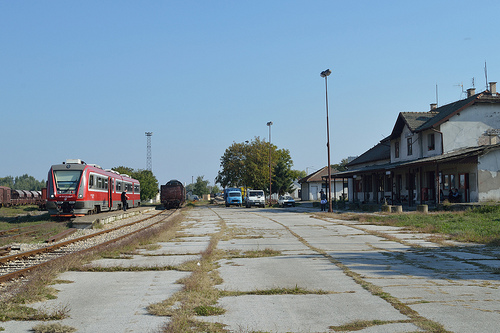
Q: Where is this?
A: This is at the road.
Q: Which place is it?
A: It is a road.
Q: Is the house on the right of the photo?
A: Yes, the house is on the right of the image.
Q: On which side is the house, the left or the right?
A: The house is on the right of the image.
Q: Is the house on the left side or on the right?
A: The house is on the right of the image.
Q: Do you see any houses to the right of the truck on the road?
A: Yes, there is a house to the right of the truck.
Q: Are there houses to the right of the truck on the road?
A: Yes, there is a house to the right of the truck.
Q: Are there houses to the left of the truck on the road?
A: No, the house is to the right of the truck.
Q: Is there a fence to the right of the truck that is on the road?
A: No, there is a house to the right of the truck.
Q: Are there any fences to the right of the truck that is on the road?
A: No, there is a house to the right of the truck.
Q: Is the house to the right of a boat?
A: No, the house is to the right of the truck.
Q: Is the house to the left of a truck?
A: No, the house is to the right of a truck.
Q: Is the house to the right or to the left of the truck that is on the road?
A: The house is to the right of the truck.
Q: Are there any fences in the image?
A: No, there are no fences.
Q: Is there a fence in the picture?
A: No, there are no fences.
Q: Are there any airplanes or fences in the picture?
A: No, there are no fences or airplanes.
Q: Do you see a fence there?
A: No, there are no fences.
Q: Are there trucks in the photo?
A: Yes, there is a truck.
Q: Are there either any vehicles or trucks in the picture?
A: Yes, there is a truck.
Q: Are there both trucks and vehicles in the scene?
A: Yes, there are both a truck and a vehicle.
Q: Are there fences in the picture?
A: No, there are no fences.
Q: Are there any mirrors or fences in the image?
A: No, there are no fences or mirrors.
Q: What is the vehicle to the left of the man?
A: The vehicle is a truck.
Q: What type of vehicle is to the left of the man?
A: The vehicle is a truck.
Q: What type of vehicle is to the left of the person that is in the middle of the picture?
A: The vehicle is a truck.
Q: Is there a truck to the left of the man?
A: Yes, there is a truck to the left of the man.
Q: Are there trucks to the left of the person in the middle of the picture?
A: Yes, there is a truck to the left of the man.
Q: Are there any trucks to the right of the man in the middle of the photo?
A: No, the truck is to the left of the man.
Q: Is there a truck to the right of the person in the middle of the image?
A: No, the truck is to the left of the man.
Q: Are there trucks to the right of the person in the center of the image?
A: No, the truck is to the left of the man.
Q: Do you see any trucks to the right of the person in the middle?
A: No, the truck is to the left of the man.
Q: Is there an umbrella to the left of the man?
A: No, there is a truck to the left of the man.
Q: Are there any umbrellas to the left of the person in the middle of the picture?
A: No, there is a truck to the left of the man.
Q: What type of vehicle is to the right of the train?
A: The vehicle is a truck.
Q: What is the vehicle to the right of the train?
A: The vehicle is a truck.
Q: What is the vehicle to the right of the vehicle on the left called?
A: The vehicle is a truck.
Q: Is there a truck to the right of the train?
A: Yes, there is a truck to the right of the train.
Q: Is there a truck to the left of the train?
A: No, the truck is to the right of the train.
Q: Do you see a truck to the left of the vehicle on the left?
A: No, the truck is to the right of the train.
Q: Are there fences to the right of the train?
A: No, there is a truck to the right of the train.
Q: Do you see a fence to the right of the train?
A: No, there is a truck to the right of the train.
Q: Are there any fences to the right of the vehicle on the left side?
A: No, there is a truck to the right of the train.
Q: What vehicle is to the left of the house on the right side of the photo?
A: The vehicle is a truck.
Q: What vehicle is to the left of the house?
A: The vehicle is a truck.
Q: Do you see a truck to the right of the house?
A: No, the truck is to the left of the house.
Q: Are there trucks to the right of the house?
A: No, the truck is to the left of the house.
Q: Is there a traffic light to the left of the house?
A: No, there is a truck to the left of the house.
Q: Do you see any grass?
A: Yes, there is grass.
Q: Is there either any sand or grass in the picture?
A: Yes, there is grass.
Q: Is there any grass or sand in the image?
A: Yes, there is grass.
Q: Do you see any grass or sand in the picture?
A: Yes, there is grass.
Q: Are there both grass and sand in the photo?
A: No, there is grass but no sand.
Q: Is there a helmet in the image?
A: No, there are no helmets.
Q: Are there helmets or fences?
A: No, there are no helmets or fences.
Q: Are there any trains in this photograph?
A: Yes, there is a train.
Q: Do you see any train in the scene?
A: Yes, there is a train.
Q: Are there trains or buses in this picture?
A: Yes, there is a train.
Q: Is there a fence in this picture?
A: No, there are no fences.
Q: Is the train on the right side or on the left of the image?
A: The train is on the left of the image.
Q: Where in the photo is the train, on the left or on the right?
A: The train is on the left of the image.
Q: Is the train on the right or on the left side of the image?
A: The train is on the left of the image.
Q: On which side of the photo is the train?
A: The train is on the left of the image.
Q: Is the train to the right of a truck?
A: No, the train is to the left of a truck.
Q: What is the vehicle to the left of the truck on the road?
A: The vehicle is a train.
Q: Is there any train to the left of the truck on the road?
A: Yes, there is a train to the left of the truck.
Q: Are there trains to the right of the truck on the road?
A: No, the train is to the left of the truck.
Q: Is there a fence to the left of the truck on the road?
A: No, there is a train to the left of the truck.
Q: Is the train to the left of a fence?
A: No, the train is to the left of the truck.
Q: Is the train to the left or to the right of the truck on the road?
A: The train is to the left of the truck.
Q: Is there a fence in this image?
A: No, there are no fences.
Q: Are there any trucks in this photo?
A: Yes, there is a truck.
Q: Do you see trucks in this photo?
A: Yes, there is a truck.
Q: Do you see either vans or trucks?
A: Yes, there is a truck.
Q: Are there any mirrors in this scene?
A: No, there are no mirrors.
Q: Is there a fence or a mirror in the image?
A: No, there are no mirrors or fences.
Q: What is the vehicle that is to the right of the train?
A: The vehicle is a truck.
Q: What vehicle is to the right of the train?
A: The vehicle is a truck.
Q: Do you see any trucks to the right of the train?
A: Yes, there is a truck to the right of the train.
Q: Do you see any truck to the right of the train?
A: Yes, there is a truck to the right of the train.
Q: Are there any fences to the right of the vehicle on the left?
A: No, there is a truck to the right of the train.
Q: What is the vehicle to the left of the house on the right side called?
A: The vehicle is a truck.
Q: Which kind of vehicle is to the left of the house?
A: The vehicle is a truck.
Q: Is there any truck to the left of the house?
A: Yes, there is a truck to the left of the house.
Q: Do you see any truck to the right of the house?
A: No, the truck is to the left of the house.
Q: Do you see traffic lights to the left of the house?
A: No, there is a truck to the left of the house.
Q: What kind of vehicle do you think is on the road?
A: The vehicle is a truck.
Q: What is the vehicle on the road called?
A: The vehicle is a truck.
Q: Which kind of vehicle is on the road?
A: The vehicle is a truck.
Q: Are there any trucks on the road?
A: Yes, there is a truck on the road.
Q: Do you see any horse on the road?
A: No, there is a truck on the road.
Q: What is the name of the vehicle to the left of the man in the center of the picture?
A: The vehicle is a truck.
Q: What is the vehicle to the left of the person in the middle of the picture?
A: The vehicle is a truck.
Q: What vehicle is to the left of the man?
A: The vehicle is a truck.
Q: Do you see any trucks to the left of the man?
A: Yes, there is a truck to the left of the man.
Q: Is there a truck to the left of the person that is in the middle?
A: Yes, there is a truck to the left of the man.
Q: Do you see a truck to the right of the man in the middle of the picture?
A: No, the truck is to the left of the man.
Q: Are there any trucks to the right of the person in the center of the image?
A: No, the truck is to the left of the man.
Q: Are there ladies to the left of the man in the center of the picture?
A: No, there is a truck to the left of the man.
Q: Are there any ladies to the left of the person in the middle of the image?
A: No, there is a truck to the left of the man.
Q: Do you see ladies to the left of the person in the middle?
A: No, there is a truck to the left of the man.